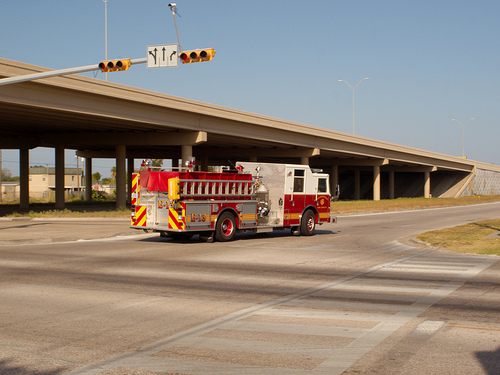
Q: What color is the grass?
A: Green.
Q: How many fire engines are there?
A: One.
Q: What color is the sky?
A: Blue.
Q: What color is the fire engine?
A: Red and white.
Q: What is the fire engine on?
A: The road.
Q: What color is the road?
A: Gray.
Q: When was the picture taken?
A: Daytime.